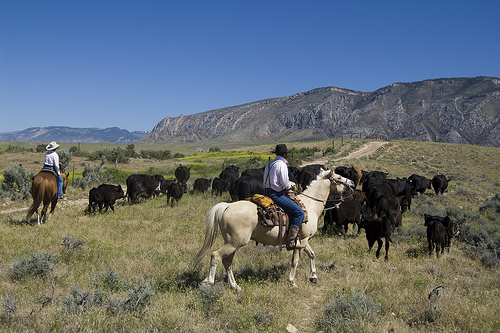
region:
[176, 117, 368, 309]
Man is riding a horse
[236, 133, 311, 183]
Man is wearing a black hat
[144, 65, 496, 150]
A mountain is in the background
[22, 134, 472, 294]
Two men on horses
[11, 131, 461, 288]
Two men on horse rounding up animals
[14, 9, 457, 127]
The sky is clear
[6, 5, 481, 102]
The sky is blue in color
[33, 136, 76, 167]
Man's hat in the background is white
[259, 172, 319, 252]
Man is wearing blue jeans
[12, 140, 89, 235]
Man's horse in the background is brown colored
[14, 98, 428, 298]
men herding cattle out west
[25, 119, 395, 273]
two cowboys on horseback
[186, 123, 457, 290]
cowboy on palomino horse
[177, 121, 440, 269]
man in black hat herds cattle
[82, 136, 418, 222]
herd of black cattle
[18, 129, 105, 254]
person on red horse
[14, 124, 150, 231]
person in white hat herds cattle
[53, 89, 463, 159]
western mountain range in distance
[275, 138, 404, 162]
dirt road through field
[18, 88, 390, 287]
old fashioned cattle drive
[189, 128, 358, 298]
a man riding a horse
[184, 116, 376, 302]
a man riding a white horse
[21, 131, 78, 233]
person riding a brown horse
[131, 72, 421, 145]
mountains and the skyline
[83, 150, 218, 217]
black cows being hearded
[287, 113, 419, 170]
a dirt road leads toward mountains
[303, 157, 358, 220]
a horse with a bridle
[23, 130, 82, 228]
person wearing a cowboy hat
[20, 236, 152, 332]
bushes and grass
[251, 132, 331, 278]
a person wearing jeans and boots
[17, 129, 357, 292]
two people on horses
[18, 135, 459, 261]
black cows near horses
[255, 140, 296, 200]
man wearing suspenders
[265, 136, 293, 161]
man wearing a black hat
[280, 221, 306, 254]
man's cowboy boot in stirrup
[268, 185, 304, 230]
man wearing blue jeans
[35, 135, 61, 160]
person wearing a white cowboy hat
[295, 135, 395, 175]
a dirt road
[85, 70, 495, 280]
a low hill near the cows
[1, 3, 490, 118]
the sky appears blue and cloudless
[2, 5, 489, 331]
Outside, rural setting.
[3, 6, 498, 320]
Outdoor, daytime scene, featuring rugged terrain and domesticated animals.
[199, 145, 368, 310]
Man seated atop white horse.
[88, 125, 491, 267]
Herd of predominantly black cattle, scattered ahead of horses.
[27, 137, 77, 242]
Second rider, following herd on brown horse.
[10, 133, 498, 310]
Hills with patchy grass, cut with dirt path.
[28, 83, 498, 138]
Steeper, more barren hills, visible in distance.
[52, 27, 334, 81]
Deep, blue, cloudless sky.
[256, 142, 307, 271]
Black hat, white shirt, blue pants and boots on rider.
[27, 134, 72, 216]
White hat, white shirt, blue pants on second rider.